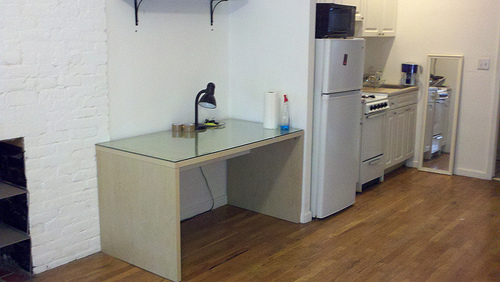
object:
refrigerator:
[311, 36, 363, 220]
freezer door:
[320, 39, 364, 94]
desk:
[97, 118, 304, 282]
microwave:
[314, 3, 357, 39]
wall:
[3, 0, 230, 275]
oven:
[358, 111, 385, 183]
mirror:
[417, 54, 462, 176]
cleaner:
[279, 94, 290, 134]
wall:
[401, 2, 498, 180]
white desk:
[98, 118, 305, 282]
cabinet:
[362, 1, 397, 37]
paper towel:
[263, 90, 277, 130]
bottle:
[281, 94, 290, 133]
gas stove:
[358, 91, 389, 192]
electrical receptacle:
[477, 58, 491, 70]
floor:
[0, 160, 497, 282]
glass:
[422, 59, 456, 170]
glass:
[95, 97, 305, 163]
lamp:
[194, 82, 218, 131]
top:
[94, 118, 304, 163]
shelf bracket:
[133, 0, 141, 26]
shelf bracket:
[208, 0, 226, 25]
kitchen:
[305, 0, 496, 225]